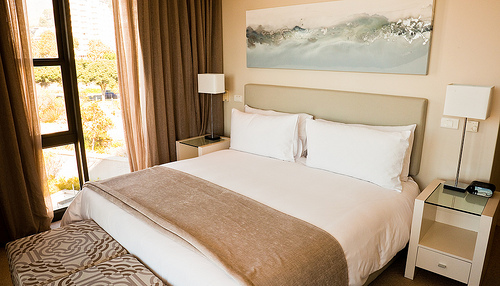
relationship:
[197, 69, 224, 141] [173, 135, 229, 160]
lamp sitting on night stand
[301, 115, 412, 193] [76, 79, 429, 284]
pillows on bed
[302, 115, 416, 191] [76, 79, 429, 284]
pillows on bed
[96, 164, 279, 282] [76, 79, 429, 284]
bedspread on bed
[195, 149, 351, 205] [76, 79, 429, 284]
cover on bed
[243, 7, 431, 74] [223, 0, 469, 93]
painting on wall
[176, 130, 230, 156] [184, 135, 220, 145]
night stand with table top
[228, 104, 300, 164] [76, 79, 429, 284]
pillow on bed